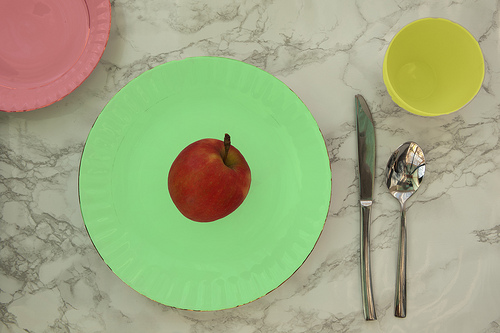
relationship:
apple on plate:
[182, 137, 248, 201] [226, 69, 309, 137]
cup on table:
[392, 31, 478, 109] [284, 18, 343, 67]